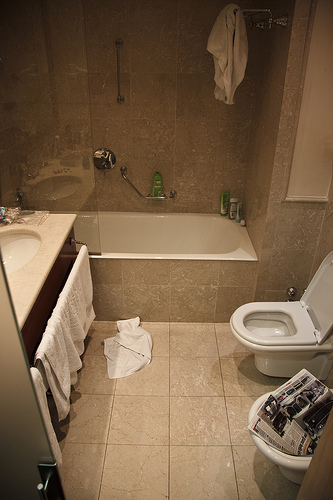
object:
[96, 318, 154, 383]
towel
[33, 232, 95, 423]
bar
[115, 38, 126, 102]
bar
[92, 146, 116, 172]
knob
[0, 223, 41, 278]
sink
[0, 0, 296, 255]
shower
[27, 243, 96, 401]
rod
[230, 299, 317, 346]
toilet seat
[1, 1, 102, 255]
glass door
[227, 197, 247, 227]
products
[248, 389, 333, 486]
basin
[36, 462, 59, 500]
handle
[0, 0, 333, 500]
bathroom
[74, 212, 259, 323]
bathtub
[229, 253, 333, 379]
toilet bowl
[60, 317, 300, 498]
floor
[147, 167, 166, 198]
green bottle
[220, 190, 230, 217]
green bottle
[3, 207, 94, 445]
vanity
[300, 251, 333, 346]
lid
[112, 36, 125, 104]
handle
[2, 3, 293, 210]
shower wall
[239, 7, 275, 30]
shower head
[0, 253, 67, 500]
bathroom door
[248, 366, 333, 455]
magazines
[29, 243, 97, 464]
towel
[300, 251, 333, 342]
toilet lid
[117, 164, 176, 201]
rail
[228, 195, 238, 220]
soap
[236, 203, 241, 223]
soap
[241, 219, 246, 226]
soap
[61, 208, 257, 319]
tub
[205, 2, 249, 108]
towel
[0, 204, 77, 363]
counter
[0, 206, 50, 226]
bag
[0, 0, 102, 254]
shower door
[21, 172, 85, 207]
sink